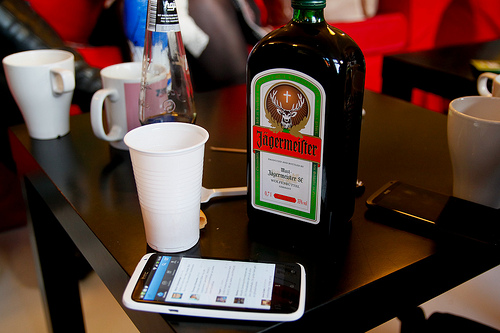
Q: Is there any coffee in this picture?
A: Yes, there is coffee.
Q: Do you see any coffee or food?
A: Yes, there is coffee.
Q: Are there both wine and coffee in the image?
A: No, there is coffee but no wine.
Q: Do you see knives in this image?
A: No, there are no knives.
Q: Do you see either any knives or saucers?
A: No, there are no knives or saucers.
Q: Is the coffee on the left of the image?
A: Yes, the coffee is on the left of the image.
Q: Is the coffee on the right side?
A: No, the coffee is on the left of the image.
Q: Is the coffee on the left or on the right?
A: The coffee is on the left of the image.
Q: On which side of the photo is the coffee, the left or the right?
A: The coffee is on the left of the image.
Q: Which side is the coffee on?
A: The coffee is on the left of the image.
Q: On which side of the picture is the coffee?
A: The coffee is on the left of the image.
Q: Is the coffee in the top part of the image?
A: Yes, the coffee is in the top of the image.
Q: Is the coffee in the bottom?
A: No, the coffee is in the top of the image.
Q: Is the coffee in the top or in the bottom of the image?
A: The coffee is in the top of the image.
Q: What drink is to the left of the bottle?
A: The drink is coffee.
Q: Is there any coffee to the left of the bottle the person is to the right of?
A: Yes, there is coffee to the left of the bottle.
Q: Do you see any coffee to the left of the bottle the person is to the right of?
A: Yes, there is coffee to the left of the bottle.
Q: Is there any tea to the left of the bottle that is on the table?
A: No, there is coffee to the left of the bottle.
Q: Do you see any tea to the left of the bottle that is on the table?
A: No, there is coffee to the left of the bottle.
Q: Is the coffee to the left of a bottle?
A: Yes, the coffee is to the left of a bottle.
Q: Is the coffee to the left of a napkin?
A: No, the coffee is to the left of a bottle.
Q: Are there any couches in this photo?
A: Yes, there is a couch.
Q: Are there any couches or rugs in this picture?
A: Yes, there is a couch.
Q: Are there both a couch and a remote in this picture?
A: No, there is a couch but no remote controls.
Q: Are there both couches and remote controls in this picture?
A: No, there is a couch but no remote controls.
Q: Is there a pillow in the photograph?
A: No, there are no pillows.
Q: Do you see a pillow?
A: No, there are no pillows.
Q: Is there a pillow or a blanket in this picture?
A: No, there are no pillows or blankets.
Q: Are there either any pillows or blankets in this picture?
A: No, there are no pillows or blankets.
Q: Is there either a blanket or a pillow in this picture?
A: No, there are no pillows or blankets.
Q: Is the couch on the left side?
A: Yes, the couch is on the left of the image.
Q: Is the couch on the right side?
A: No, the couch is on the left of the image.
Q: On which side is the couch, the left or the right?
A: The couch is on the left of the image.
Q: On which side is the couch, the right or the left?
A: The couch is on the left of the image.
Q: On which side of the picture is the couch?
A: The couch is on the left of the image.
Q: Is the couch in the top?
A: Yes, the couch is in the top of the image.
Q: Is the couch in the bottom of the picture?
A: No, the couch is in the top of the image.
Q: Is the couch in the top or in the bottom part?
A: The couch is in the top of the image.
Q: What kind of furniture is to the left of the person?
A: The piece of furniture is a couch.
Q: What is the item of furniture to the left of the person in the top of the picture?
A: The piece of furniture is a couch.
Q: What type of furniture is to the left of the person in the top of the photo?
A: The piece of furniture is a couch.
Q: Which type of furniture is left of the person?
A: The piece of furniture is a couch.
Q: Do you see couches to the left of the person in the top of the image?
A: Yes, there is a couch to the left of the person.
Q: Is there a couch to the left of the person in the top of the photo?
A: Yes, there is a couch to the left of the person.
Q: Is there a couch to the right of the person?
A: No, the couch is to the left of the person.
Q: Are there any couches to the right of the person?
A: No, the couch is to the left of the person.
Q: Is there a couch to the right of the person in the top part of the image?
A: No, the couch is to the left of the person.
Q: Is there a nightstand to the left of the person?
A: No, there is a couch to the left of the person.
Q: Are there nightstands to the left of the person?
A: No, there is a couch to the left of the person.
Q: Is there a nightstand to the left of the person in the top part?
A: No, there is a couch to the left of the person.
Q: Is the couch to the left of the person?
A: Yes, the couch is to the left of the person.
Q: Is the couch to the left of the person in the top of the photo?
A: Yes, the couch is to the left of the person.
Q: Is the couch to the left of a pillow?
A: No, the couch is to the left of the person.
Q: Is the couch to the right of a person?
A: No, the couch is to the left of a person.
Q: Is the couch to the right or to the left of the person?
A: The couch is to the left of the person.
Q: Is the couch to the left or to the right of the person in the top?
A: The couch is to the left of the person.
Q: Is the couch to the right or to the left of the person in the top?
A: The couch is to the left of the person.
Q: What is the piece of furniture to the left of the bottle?
A: The piece of furniture is a couch.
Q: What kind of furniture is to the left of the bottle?
A: The piece of furniture is a couch.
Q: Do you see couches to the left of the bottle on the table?
A: Yes, there is a couch to the left of the bottle.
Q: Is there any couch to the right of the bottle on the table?
A: No, the couch is to the left of the bottle.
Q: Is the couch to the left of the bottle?
A: Yes, the couch is to the left of the bottle.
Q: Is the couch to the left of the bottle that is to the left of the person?
A: Yes, the couch is to the left of the bottle.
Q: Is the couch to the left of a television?
A: No, the couch is to the left of the bottle.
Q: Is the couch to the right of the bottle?
A: No, the couch is to the left of the bottle.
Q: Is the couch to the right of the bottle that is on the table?
A: No, the couch is to the left of the bottle.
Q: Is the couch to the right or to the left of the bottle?
A: The couch is to the left of the bottle.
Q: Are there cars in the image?
A: No, there are no cars.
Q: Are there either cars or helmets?
A: No, there are no cars or helmets.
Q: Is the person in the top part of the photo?
A: Yes, the person is in the top of the image.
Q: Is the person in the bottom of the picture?
A: No, the person is in the top of the image.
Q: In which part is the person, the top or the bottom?
A: The person is in the top of the image.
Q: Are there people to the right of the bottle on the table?
A: Yes, there is a person to the right of the bottle.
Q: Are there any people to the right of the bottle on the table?
A: Yes, there is a person to the right of the bottle.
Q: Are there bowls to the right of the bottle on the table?
A: No, there is a person to the right of the bottle.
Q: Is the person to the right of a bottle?
A: Yes, the person is to the right of a bottle.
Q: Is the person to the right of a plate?
A: No, the person is to the right of a bottle.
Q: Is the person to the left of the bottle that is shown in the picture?
A: No, the person is to the right of the bottle.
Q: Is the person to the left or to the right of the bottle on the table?
A: The person is to the right of the bottle.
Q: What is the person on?
A: The person is on the couch.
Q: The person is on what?
A: The person is on the couch.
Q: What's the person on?
A: The person is on the couch.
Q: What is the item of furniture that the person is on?
A: The piece of furniture is a couch.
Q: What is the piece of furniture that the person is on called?
A: The piece of furniture is a couch.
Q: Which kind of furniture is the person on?
A: The person is on the couch.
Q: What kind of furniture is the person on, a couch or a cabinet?
A: The person is on a couch.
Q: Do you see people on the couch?
A: Yes, there is a person on the couch.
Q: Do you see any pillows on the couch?
A: No, there is a person on the couch.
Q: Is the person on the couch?
A: Yes, the person is on the couch.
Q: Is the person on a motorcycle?
A: No, the person is on the couch.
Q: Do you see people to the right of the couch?
A: Yes, there is a person to the right of the couch.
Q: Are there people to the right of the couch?
A: Yes, there is a person to the right of the couch.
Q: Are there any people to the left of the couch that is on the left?
A: No, the person is to the right of the couch.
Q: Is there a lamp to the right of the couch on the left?
A: No, there is a person to the right of the couch.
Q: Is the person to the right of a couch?
A: Yes, the person is to the right of a couch.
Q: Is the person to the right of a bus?
A: No, the person is to the right of a couch.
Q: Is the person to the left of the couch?
A: No, the person is to the right of the couch.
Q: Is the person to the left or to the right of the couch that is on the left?
A: The person is to the right of the couch.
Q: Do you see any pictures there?
A: No, there are no pictures.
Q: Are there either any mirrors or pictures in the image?
A: No, there are no pictures or mirrors.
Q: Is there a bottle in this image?
A: Yes, there is a bottle.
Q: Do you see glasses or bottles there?
A: Yes, there is a bottle.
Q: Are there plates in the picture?
A: No, there are no plates.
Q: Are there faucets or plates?
A: No, there are no plates or faucets.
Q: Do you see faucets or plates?
A: No, there are no plates or faucets.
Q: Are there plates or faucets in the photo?
A: No, there are no plates or faucets.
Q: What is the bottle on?
A: The bottle is on the table.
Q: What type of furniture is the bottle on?
A: The bottle is on the table.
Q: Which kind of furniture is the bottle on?
A: The bottle is on the table.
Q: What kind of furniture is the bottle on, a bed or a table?
A: The bottle is on a table.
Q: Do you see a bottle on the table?
A: Yes, there is a bottle on the table.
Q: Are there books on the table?
A: No, there is a bottle on the table.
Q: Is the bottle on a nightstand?
A: No, the bottle is on a table.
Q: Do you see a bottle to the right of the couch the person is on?
A: Yes, there is a bottle to the right of the couch.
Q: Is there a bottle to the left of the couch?
A: No, the bottle is to the right of the couch.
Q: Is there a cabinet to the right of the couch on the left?
A: No, there is a bottle to the right of the couch.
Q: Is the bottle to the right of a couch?
A: Yes, the bottle is to the right of a couch.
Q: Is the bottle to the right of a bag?
A: No, the bottle is to the right of a couch.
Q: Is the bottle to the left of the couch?
A: No, the bottle is to the right of the couch.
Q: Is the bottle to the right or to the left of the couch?
A: The bottle is to the right of the couch.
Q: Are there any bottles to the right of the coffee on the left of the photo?
A: Yes, there is a bottle to the right of the coffee.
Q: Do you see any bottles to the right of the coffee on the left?
A: Yes, there is a bottle to the right of the coffee.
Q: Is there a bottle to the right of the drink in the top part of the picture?
A: Yes, there is a bottle to the right of the coffee.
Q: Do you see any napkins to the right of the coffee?
A: No, there is a bottle to the right of the coffee.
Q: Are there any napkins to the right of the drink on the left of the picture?
A: No, there is a bottle to the right of the coffee.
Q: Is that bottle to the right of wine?
A: No, the bottle is to the right of the coffee.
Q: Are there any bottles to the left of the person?
A: Yes, there is a bottle to the left of the person.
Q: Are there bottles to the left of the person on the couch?
A: Yes, there is a bottle to the left of the person.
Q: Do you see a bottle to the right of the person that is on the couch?
A: No, the bottle is to the left of the person.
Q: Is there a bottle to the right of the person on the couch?
A: No, the bottle is to the left of the person.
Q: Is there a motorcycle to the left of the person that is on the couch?
A: No, there is a bottle to the left of the person.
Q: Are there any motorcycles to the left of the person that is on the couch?
A: No, there is a bottle to the left of the person.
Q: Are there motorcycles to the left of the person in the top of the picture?
A: No, there is a bottle to the left of the person.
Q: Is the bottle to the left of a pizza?
A: No, the bottle is to the left of the person.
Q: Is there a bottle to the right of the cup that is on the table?
A: Yes, there is a bottle to the right of the cup.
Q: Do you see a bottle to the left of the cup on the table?
A: No, the bottle is to the right of the cup.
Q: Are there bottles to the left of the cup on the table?
A: No, the bottle is to the right of the cup.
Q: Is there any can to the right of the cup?
A: No, there is a bottle to the right of the cup.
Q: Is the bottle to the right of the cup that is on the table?
A: Yes, the bottle is to the right of the cup.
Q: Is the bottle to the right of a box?
A: No, the bottle is to the right of the cup.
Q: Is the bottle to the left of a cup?
A: No, the bottle is to the right of a cup.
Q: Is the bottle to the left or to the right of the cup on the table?
A: The bottle is to the right of the cup.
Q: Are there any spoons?
A: Yes, there is a spoon.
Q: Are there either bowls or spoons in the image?
A: Yes, there is a spoon.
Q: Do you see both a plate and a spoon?
A: No, there is a spoon but no plates.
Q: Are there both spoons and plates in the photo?
A: No, there is a spoon but no plates.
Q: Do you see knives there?
A: No, there are no knives.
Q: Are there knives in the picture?
A: No, there are no knives.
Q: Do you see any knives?
A: No, there are no knives.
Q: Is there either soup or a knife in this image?
A: No, there are no knives or soup.